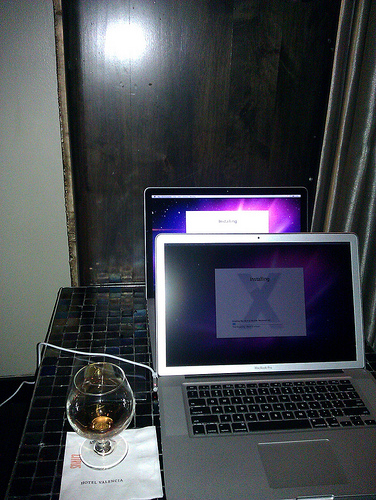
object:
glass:
[65, 361, 137, 470]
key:
[192, 424, 205, 435]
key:
[190, 406, 212, 415]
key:
[210, 389, 223, 396]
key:
[234, 388, 247, 396]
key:
[278, 395, 290, 403]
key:
[296, 400, 310, 410]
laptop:
[143, 184, 309, 367]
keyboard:
[179, 380, 376, 437]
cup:
[65, 359, 137, 475]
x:
[237, 271, 285, 332]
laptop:
[151, 234, 374, 497]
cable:
[0, 339, 156, 407]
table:
[0, 270, 375, 500]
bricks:
[105, 340, 120, 348]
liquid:
[67, 377, 136, 436]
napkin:
[55, 424, 165, 500]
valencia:
[76, 477, 125, 484]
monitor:
[164, 241, 357, 365]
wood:
[53, 0, 373, 295]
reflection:
[79, 6, 167, 83]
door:
[51, 2, 373, 289]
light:
[102, 21, 152, 66]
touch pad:
[256, 437, 350, 489]